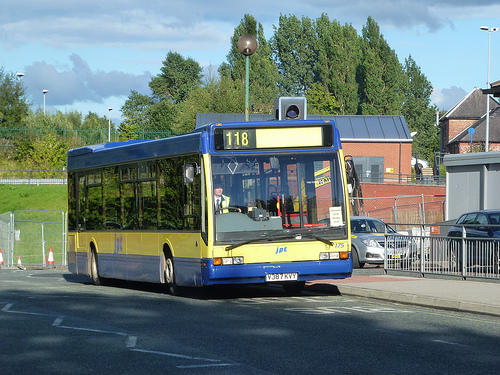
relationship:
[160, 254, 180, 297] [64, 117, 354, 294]
tire of bus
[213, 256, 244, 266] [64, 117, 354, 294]
lights on bus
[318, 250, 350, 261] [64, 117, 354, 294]
lights on bus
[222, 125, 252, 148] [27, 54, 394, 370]
number on bus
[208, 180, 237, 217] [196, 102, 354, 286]
bus driver on bus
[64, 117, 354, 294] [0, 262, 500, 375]
bus on street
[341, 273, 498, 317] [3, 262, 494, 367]
sidewalk on street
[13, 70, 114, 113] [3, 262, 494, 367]
lights on street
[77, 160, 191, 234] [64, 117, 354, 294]
windows on bus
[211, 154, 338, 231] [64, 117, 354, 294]
window on bus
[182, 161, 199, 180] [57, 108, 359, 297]
mirror on bus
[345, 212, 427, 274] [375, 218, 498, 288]
car near bicycle rack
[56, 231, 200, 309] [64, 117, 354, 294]
wheels in bus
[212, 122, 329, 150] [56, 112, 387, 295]
route number for bus